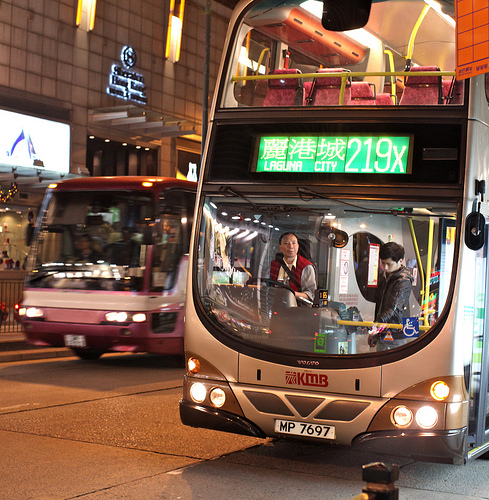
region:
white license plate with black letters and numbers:
[254, 418, 334, 443]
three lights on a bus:
[386, 375, 465, 439]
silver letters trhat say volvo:
[281, 346, 326, 373]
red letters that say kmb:
[258, 364, 335, 405]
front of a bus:
[172, 228, 438, 431]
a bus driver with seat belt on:
[238, 220, 313, 338]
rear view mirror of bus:
[308, 223, 361, 262]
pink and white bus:
[0, 223, 187, 403]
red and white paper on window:
[352, 239, 379, 298]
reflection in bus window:
[173, 218, 274, 366]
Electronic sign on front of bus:
[245, 128, 417, 185]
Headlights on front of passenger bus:
[382, 395, 437, 427]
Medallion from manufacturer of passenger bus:
[293, 356, 326, 369]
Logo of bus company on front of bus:
[281, 367, 334, 392]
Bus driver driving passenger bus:
[257, 222, 323, 321]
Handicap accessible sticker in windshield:
[396, 313, 428, 347]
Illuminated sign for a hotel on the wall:
[102, 42, 171, 109]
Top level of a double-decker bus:
[213, 9, 486, 107]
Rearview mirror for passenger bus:
[457, 179, 487, 252]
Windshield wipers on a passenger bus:
[204, 185, 456, 229]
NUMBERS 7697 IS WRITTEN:
[318, 421, 328, 444]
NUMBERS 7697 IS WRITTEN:
[306, 424, 317, 440]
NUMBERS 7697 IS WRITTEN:
[314, 419, 326, 460]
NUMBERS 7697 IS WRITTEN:
[305, 415, 319, 459]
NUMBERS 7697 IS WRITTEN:
[296, 408, 314, 467]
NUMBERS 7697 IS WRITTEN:
[320, 425, 324, 442]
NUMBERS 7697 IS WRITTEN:
[309, 433, 323, 436]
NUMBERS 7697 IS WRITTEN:
[308, 424, 322, 446]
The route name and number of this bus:
[237, 124, 415, 177]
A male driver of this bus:
[266, 230, 323, 301]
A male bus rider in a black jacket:
[371, 242, 407, 349]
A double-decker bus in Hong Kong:
[198, 6, 461, 411]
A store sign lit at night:
[96, 36, 149, 105]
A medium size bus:
[9, 168, 176, 339]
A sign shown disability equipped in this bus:
[398, 314, 424, 338]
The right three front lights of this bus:
[172, 354, 241, 415]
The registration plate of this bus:
[272, 417, 346, 442]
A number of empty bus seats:
[265, 57, 392, 103]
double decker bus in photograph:
[226, 39, 487, 483]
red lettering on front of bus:
[276, 354, 354, 408]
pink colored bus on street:
[29, 146, 192, 368]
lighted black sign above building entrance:
[107, 40, 146, 118]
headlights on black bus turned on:
[184, 352, 470, 445]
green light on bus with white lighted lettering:
[265, 128, 432, 192]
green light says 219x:
[349, 129, 421, 186]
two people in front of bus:
[276, 203, 435, 324]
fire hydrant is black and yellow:
[331, 428, 412, 497]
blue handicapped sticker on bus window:
[395, 304, 434, 359]